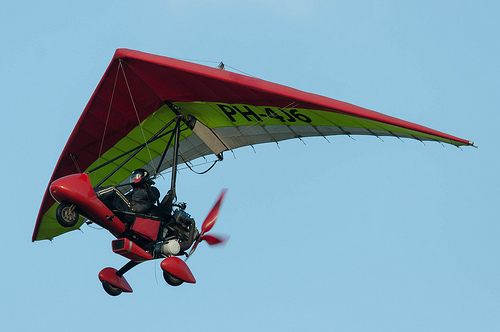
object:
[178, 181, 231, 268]
propellor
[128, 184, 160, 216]
jacket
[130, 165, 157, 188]
helmet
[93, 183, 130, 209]
pants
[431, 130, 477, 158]
wing tip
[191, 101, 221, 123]
yellow part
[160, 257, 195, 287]
wheels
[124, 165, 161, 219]
man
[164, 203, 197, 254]
engine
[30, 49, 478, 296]
aircraft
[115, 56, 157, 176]
strings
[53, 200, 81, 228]
tire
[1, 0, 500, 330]
sky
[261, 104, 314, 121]
numbers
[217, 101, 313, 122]
letters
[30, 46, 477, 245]
wing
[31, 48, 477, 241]
kite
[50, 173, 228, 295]
car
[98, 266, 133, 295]
gear wheel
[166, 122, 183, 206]
support pole